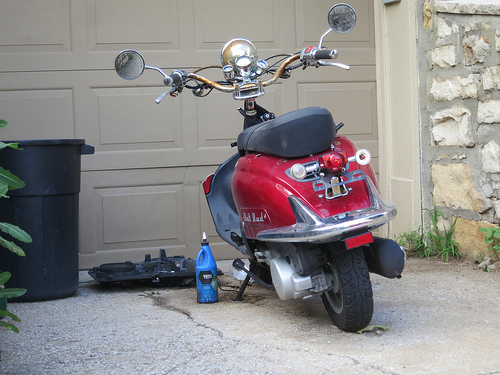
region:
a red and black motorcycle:
[120, 3, 411, 320]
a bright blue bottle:
[187, 231, 219, 306]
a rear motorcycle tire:
[300, 239, 375, 328]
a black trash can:
[1, 137, 97, 304]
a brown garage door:
[0, 4, 390, 279]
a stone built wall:
[421, 0, 493, 255]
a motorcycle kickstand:
[227, 258, 254, 300]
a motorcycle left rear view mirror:
[111, 49, 166, 91]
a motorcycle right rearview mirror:
[317, 4, 354, 50]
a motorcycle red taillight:
[315, 147, 347, 180]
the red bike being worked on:
[117, 12, 413, 331]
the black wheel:
[320, 241, 375, 329]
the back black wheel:
[321, 249, 380, 336]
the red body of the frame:
[230, 147, 308, 228]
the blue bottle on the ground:
[195, 230, 215, 305]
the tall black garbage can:
[5, 130, 95, 310]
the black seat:
[240, 103, 335, 153]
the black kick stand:
[230, 260, 255, 303]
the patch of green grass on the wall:
[396, 206, 473, 262]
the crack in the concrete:
[137, 286, 227, 358]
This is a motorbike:
[91, 3, 421, 343]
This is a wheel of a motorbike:
[302, 237, 382, 339]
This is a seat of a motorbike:
[222, 101, 351, 158]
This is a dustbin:
[0, 130, 102, 308]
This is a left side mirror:
[110, 39, 151, 84]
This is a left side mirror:
[325, 2, 359, 35]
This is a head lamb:
[217, 35, 262, 75]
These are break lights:
[285, 145, 391, 182]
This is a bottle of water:
[190, 225, 225, 317]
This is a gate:
[0, 1, 396, 282]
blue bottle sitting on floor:
[195, 220, 223, 305]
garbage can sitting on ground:
[0, 125, 98, 307]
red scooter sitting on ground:
[112, 7, 440, 334]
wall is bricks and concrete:
[409, 6, 498, 276]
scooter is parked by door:
[108, 0, 430, 337]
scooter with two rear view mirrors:
[104, 4, 399, 113]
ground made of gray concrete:
[35, 279, 483, 365]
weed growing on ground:
[402, 209, 497, 286]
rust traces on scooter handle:
[172, 30, 328, 105]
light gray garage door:
[1, 5, 433, 282]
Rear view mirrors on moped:
[114, 0, 360, 80]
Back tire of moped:
[308, 247, 382, 337]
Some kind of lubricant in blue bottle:
[175, 225, 236, 317]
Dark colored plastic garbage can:
[0, 110, 95, 305]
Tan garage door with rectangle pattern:
[1, 2, 293, 254]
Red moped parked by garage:
[131, 1, 373, 352]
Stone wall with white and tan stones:
[406, 0, 498, 239]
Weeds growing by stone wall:
[401, 225, 491, 272]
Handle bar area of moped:
[151, 55, 363, 104]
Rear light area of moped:
[268, 147, 377, 184]